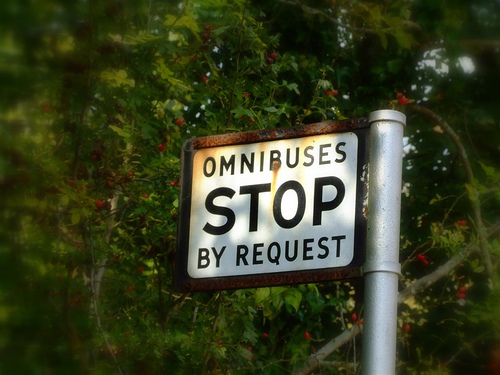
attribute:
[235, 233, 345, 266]
word — REQUEST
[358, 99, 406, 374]
pole — metal, gray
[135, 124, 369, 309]
sign — bus stop 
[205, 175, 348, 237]
stop — black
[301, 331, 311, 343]
berry — red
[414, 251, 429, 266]
berry — red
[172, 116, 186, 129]
berry — red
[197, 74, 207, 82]
berry — red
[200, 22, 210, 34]
berry — red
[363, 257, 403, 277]
bracket — metal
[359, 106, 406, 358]
pole — gray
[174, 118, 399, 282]
sign — metal, framed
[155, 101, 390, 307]
pole — gray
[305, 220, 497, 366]
branch — wooden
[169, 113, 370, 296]
sign — for bus stop 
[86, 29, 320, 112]
leaves — green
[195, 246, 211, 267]
letter — B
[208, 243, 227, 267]
letter — Y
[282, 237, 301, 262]
letter — U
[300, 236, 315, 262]
letter — E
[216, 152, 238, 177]
letter — M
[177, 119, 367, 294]
frame — rusted, metal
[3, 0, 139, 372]
tree — blurry, leaf covered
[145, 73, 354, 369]
tree — blurry, leaf covered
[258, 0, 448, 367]
tree — blurry, leaf covered